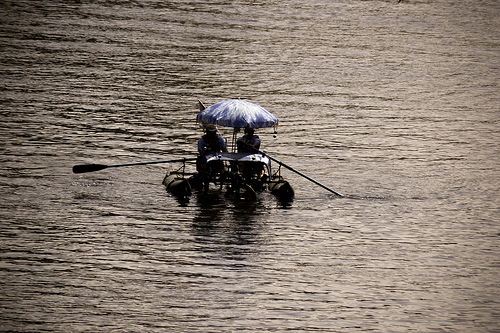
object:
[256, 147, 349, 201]
oar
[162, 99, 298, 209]
boat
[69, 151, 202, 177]
oar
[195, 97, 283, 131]
umbrella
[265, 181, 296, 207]
cylinder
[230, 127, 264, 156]
person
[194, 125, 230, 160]
person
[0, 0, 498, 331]
water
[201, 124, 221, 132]
hat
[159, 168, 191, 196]
cylinder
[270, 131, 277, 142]
balls